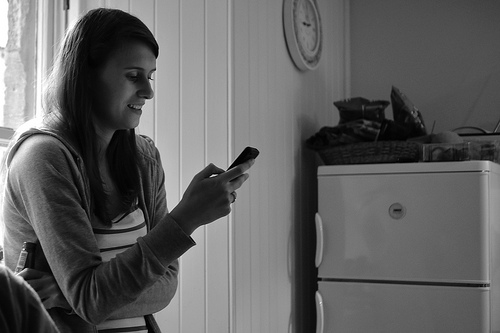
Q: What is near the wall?
A: Ice box.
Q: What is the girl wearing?
A: Shirt.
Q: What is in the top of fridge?
A: Basket.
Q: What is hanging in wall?
A: Clcok.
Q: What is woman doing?
A: Texting.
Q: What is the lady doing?
A: Texting.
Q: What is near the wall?
A: Freezer.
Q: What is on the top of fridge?
A: Goodies.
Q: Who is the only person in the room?
A: A woman on a cell phone.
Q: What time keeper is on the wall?
A: A clock.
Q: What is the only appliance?
A: A refrigerator.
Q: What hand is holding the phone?
A: Right hand.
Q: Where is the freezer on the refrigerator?
A: On top.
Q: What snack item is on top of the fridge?
A: Chips.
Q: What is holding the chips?
A: A basket.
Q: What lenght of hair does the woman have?
A: Long.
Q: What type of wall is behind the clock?
A: Paneled wall.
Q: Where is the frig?
A: In the corner.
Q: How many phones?
A: 1.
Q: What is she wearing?
A: Sweater.